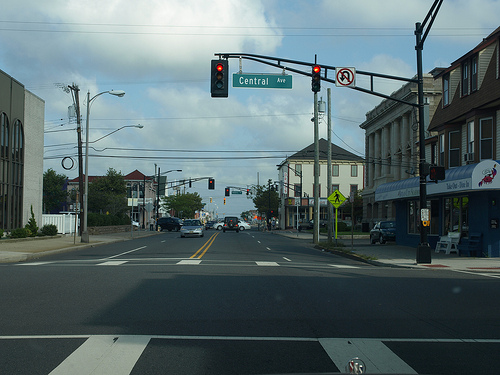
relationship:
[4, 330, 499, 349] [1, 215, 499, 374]
line in road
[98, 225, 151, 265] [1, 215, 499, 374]
line in road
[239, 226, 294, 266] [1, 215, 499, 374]
line in road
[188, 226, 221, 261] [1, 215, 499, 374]
line in road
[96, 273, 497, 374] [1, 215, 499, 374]
shadow in road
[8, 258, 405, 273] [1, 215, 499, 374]
crosswalk in road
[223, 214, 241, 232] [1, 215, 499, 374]
jeep on road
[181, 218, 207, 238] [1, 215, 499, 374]
car on road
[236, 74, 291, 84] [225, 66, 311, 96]
"central ave" written on board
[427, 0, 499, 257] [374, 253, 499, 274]
business on corner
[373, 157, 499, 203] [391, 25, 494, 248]
awning over store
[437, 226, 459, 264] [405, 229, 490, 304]
chair on sidewalk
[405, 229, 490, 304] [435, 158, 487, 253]
sidewalk in front of restaurant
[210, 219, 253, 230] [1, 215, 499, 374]
car on road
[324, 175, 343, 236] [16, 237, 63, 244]
sign at sidewalk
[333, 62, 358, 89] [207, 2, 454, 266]
sign on post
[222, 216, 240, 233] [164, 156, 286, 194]
jeep waiting at light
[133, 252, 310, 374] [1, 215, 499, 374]
lines on road